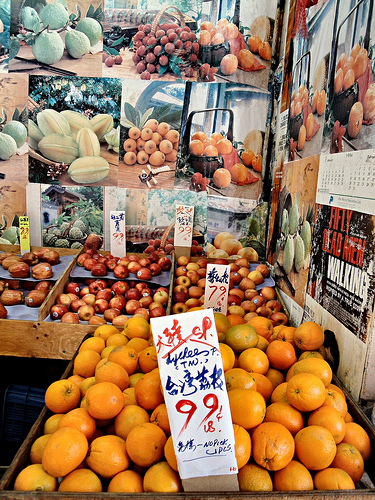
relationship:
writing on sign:
[154, 315, 238, 473] [106, 209, 133, 257]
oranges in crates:
[14, 314, 372, 494] [0, 236, 373, 496]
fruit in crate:
[1, 246, 370, 490] [71, 238, 174, 287]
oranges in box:
[14, 314, 372, 494] [53, 346, 110, 414]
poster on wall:
[275, 138, 325, 336] [268, 150, 374, 333]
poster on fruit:
[21, 76, 130, 191] [25, 101, 118, 188]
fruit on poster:
[119, 114, 183, 166] [115, 80, 179, 190]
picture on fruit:
[175, 110, 293, 237] [184, 128, 261, 195]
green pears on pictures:
[17, 0, 102, 65] [0, 1, 104, 77]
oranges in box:
[14, 314, 372, 494] [59, 328, 372, 492]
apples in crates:
[49, 247, 171, 323] [0, 236, 373, 496]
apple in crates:
[60, 310, 81, 325] [0, 236, 373, 496]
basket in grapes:
[133, 5, 194, 73] [129, 19, 197, 77]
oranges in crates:
[87, 334, 357, 459] [0, 236, 373, 496]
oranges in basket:
[183, 128, 263, 194] [184, 104, 237, 180]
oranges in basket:
[199, 16, 271, 81] [196, 32, 234, 61]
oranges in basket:
[288, 83, 324, 160] [286, 49, 313, 145]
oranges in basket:
[334, 45, 370, 141] [334, 2, 373, 132]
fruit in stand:
[1, 246, 370, 490] [1, 0, 372, 497]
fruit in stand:
[1, 246, 370, 490] [0, 243, 373, 497]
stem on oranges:
[294, 387, 302, 392] [14, 314, 372, 494]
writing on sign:
[155, 316, 236, 475] [148, 306, 238, 479]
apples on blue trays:
[42, 234, 170, 329] [1, 242, 275, 324]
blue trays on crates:
[1, 242, 275, 324] [5, 236, 373, 496]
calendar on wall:
[317, 13, 373, 214] [284, 5, 369, 300]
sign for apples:
[15, 217, 34, 257] [2, 244, 62, 277]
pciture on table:
[25, 76, 123, 185] [68, 147, 119, 183]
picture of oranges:
[175, 110, 293, 237] [188, 130, 262, 191]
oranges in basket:
[188, 130, 262, 191] [190, 90, 263, 212]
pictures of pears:
[7, 23, 104, 77] [24, 21, 99, 59]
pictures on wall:
[7, 23, 104, 77] [1, 23, 267, 248]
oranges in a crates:
[14, 314, 372, 494] [0, 236, 373, 496]